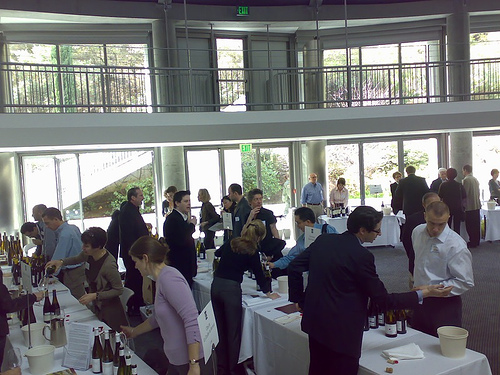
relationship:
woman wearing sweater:
[196, 216, 308, 327] [61, 244, 163, 322]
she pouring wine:
[43, 228, 137, 354] [41, 265, 55, 289]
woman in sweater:
[117, 231, 213, 373] [151, 261, 208, 365]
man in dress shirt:
[408, 191, 475, 331] [410, 226, 478, 309]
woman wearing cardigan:
[121, 236, 209, 375] [151, 272, 203, 342]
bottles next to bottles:
[384, 301, 397, 339] [395, 301, 408, 335]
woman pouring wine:
[46, 226, 126, 335] [46, 260, 59, 281]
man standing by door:
[301, 173, 327, 224] [259, 147, 296, 244]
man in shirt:
[301, 173, 327, 224] [302, 182, 324, 202]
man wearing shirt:
[413, 201, 476, 341] [404, 225, 475, 296]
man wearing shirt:
[285, 207, 453, 375] [49, 219, 83, 267]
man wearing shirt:
[161, 185, 201, 277] [300, 180, 326, 202]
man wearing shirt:
[40, 207, 87, 292] [328, 185, 348, 207]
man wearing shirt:
[301, 170, 325, 218] [248, 206, 278, 237]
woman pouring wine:
[42, 223, 127, 330] [36, 288, 53, 322]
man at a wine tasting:
[285, 207, 453, 375] [1, 145, 474, 372]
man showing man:
[260, 192, 417, 367] [409, 202, 476, 335]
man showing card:
[260, 192, 417, 367] [438, 278, 451, 292]